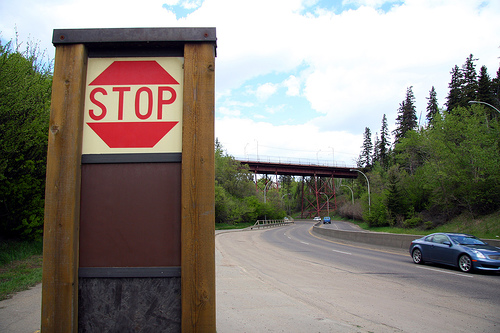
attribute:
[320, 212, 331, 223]
truck — blue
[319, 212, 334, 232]
car — compact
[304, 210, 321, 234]
car — compact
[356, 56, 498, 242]
pines — tall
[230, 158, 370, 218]
bridge — red, metal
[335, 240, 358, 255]
line — white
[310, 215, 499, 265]
barrier wall — concrete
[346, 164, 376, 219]
street light — silver, metallic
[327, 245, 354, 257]
line — white, dotted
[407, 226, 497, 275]
car — black, compact, blue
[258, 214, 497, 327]
highway — curving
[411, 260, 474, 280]
line — white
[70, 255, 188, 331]
bottom — metal